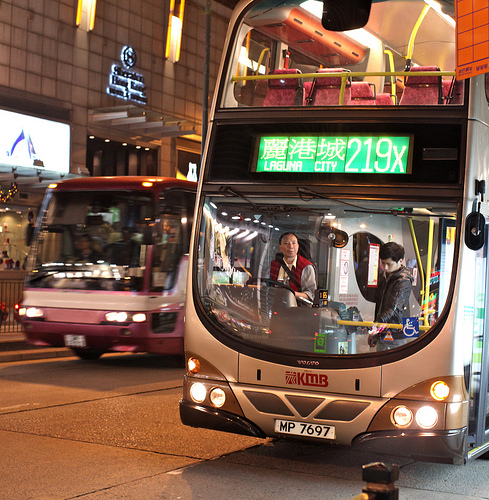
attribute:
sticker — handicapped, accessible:
[393, 310, 450, 340]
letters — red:
[296, 366, 328, 391]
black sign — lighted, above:
[105, 43, 148, 105]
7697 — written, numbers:
[298, 422, 330, 438]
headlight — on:
[417, 404, 437, 430]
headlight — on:
[389, 400, 414, 432]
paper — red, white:
[367, 242, 380, 288]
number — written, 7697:
[292, 419, 345, 439]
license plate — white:
[273, 419, 340, 440]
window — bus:
[195, 193, 459, 354]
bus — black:
[179, 0, 487, 426]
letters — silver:
[293, 354, 323, 367]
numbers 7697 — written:
[298, 421, 331, 436]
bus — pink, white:
[16, 170, 194, 364]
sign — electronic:
[263, 116, 486, 190]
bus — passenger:
[29, 152, 202, 418]